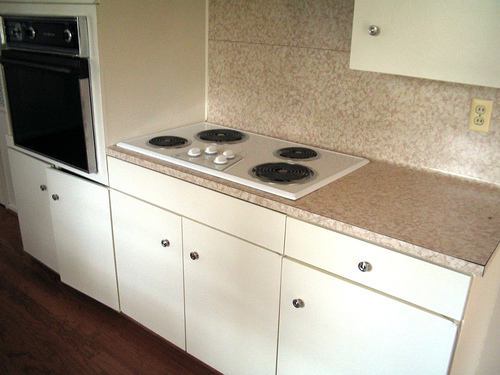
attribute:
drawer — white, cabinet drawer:
[272, 213, 474, 315]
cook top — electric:
[118, 107, 368, 203]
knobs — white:
[173, 139, 237, 170]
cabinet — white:
[340, 0, 484, 117]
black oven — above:
[1, 36, 83, 174]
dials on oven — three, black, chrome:
[184, 141, 241, 172]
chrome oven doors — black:
[6, 17, 86, 46]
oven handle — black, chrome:
[0, 46, 84, 81]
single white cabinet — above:
[353, 4, 500, 95]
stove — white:
[136, 124, 375, 214]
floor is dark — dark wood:
[6, 264, 221, 374]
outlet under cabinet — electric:
[464, 90, 493, 138]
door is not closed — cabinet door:
[3, 145, 121, 314]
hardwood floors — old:
[4, 254, 235, 372]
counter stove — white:
[139, 109, 326, 211]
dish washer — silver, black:
[2, 14, 117, 186]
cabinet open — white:
[2, 146, 120, 317]